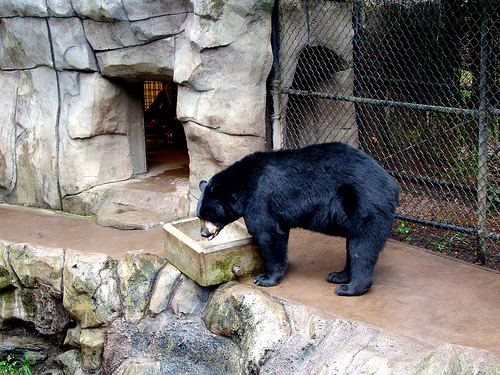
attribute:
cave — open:
[112, 61, 193, 198]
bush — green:
[1, 355, 34, 373]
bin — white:
[151, 214, 248, 281]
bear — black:
[190, 133, 417, 307]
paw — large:
[252, 268, 287, 290]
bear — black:
[199, 141, 404, 296]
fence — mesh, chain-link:
[272, 1, 498, 270]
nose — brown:
[197, 226, 214, 242]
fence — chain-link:
[302, 14, 496, 174]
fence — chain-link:
[306, 10, 491, 153]